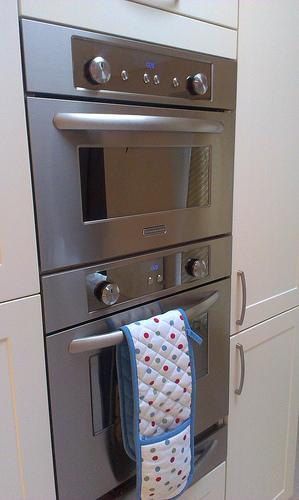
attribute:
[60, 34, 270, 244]
oven — silver, into cabinet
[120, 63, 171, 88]
display — blue